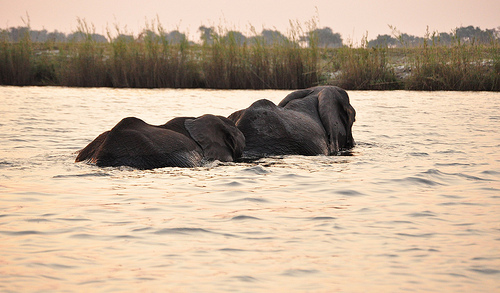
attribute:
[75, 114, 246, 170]
elephant — wet, swimming, gray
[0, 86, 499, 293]
water — river, gray, calm, large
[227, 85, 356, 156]
elephant — bigger, wrinkly skin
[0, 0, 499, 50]
sky — pink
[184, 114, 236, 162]
ear — pulled back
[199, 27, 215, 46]
tree — silhouette, distant, background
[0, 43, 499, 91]
field — tall grass, tall, grassy, dry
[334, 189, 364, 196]
wave — small